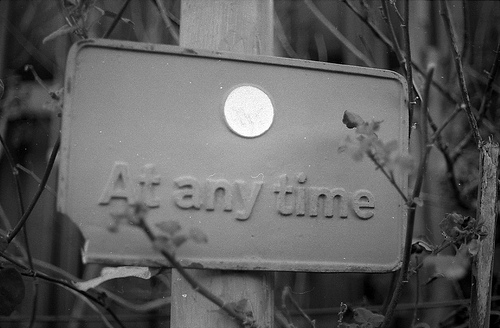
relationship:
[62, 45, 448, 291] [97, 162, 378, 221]
sign with at any time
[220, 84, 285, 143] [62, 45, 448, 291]
circle on sign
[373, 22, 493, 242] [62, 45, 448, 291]
branches around sign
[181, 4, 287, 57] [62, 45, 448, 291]
pole behind sign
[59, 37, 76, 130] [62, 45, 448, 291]
edges on sign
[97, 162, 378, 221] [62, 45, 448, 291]
at any time on sign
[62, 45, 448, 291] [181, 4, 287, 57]
sign on pole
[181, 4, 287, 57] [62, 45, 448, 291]
pole has sign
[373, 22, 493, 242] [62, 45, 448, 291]
branches near sign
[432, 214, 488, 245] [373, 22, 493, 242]
leaves on branches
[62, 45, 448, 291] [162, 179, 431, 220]
sign has writing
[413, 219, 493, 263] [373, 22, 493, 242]
flower on branches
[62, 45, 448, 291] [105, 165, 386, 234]
sign says at any time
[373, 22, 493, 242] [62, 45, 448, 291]
branches by sign